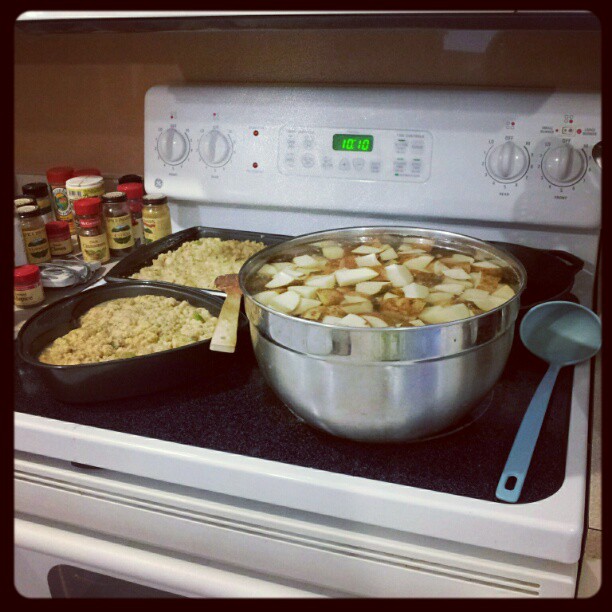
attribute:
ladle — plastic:
[492, 300, 601, 505]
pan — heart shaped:
[20, 279, 235, 396]